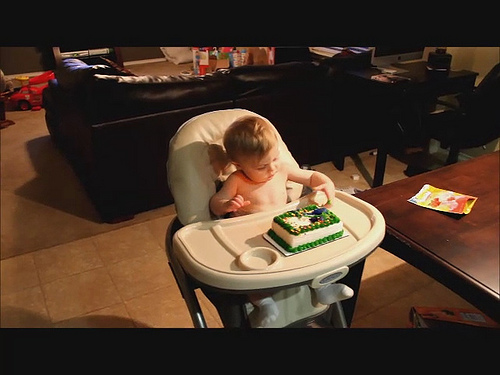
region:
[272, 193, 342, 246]
The green cake on the baby's high chair.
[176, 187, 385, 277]
The tray on the baby's high chair.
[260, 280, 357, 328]
The white socks the baby is wearing.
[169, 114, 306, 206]
The seat of the high chair.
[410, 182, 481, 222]
The card on the brown table.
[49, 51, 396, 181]
The leather sofa behind the high chair.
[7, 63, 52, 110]
The red plastic car on the left.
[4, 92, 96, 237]
The rug in the area where the sofa is placed.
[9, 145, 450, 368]
The tile in the area where the high chair is placed.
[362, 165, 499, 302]
The wooden table to the right of the high chair.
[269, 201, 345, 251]
a small green and white cake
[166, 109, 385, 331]
a baby in a highchair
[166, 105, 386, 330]
a white highchair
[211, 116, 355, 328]
a baby eating cake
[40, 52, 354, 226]
a long black leather couch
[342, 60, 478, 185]
a small black table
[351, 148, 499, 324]
corner of a brown wooden dinner table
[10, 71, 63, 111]
a plastic child's riding toy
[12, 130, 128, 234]
shadow of couch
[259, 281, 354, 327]
a pair of baby socks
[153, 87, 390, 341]
A baby sitting in a high chair.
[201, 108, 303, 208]
A baby with blonde hair.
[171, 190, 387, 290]
The tray table on a high chair.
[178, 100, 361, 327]
A baby getting ready to eat a cake.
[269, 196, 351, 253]
A green and white decorated cake.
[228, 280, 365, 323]
White socks on the baby's feet.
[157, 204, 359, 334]
The still frame of the high chair.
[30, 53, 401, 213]
A black leather couch.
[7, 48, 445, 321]
The floor is covered in tile.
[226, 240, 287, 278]
An indention for a cup or bottle.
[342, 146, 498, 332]
A wooden table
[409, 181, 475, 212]
A piece of paper on the table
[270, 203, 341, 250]
A small white and green cake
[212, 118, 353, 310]
A blonde toddler in a high chair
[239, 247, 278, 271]
The cup holder on a high chair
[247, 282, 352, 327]
A pair of white socks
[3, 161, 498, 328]
The tile floor of the kitchen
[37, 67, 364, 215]
A black corner sofa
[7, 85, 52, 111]
A red toy truck on the ground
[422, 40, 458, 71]
The base of a lamp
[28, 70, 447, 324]
baby in a high chair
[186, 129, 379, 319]
this child is about to eat cake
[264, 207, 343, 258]
the cake is white and green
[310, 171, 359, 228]
the baby is holding an object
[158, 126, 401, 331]
the highchair is white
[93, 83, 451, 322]
this high chair is in the living room area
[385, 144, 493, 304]
a wooden table in the photo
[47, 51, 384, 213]
a black couch behind the baby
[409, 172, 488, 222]
a yellow paper on the table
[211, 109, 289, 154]
a brown haired boy